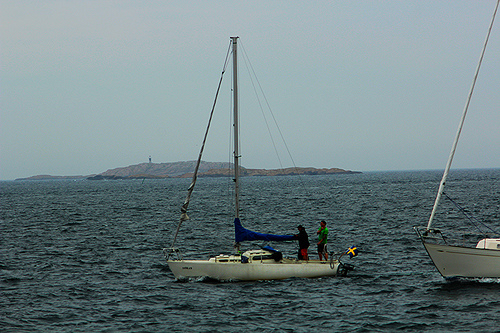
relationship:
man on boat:
[290, 218, 312, 268] [148, 13, 356, 284]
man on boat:
[314, 217, 331, 262] [148, 13, 356, 284]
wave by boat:
[172, 275, 227, 289] [147, 21, 367, 296]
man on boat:
[314, 217, 331, 262] [161, 25, 360, 284]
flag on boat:
[229, 215, 293, 247] [161, 25, 360, 284]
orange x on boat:
[346, 245, 358, 256] [165, 35, 345, 278]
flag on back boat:
[346, 242, 360, 257] [168, 250, 346, 277]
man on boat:
[290, 218, 312, 268] [121, 26, 381, 309]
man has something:
[290, 218, 312, 268] [292, 241, 312, 264]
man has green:
[314, 217, 331, 262] [314, 222, 334, 246]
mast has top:
[223, 25, 252, 73] [221, 30, 243, 50]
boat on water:
[78, 120, 296, 287] [0, 163, 499, 330]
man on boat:
[314, 217, 331, 262] [65, 102, 382, 331]